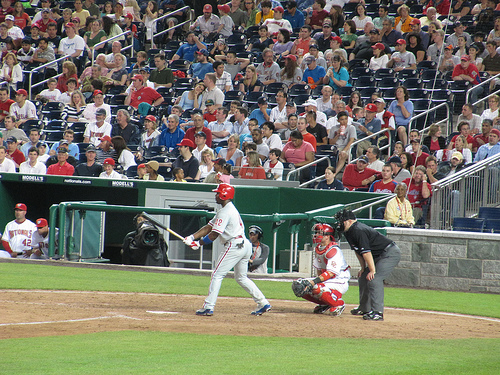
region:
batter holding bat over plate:
[138, 173, 281, 320]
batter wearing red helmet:
[138, 170, 276, 317]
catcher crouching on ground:
[288, 218, 352, 319]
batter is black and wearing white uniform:
[140, 176, 278, 326]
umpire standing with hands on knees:
[330, 202, 401, 327]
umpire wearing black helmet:
[331, 201, 410, 328]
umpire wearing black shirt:
[328, 202, 401, 326]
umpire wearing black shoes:
[333, 195, 412, 337]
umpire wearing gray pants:
[332, 201, 399, 323]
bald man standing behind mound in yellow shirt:
[381, 177, 421, 227]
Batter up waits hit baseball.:
[142, 181, 278, 328]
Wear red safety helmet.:
[210, 179, 254, 239]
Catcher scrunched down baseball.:
[289, 216, 357, 323]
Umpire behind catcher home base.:
[332, 206, 405, 333]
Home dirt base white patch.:
[22, 259, 192, 373]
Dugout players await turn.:
[4, 187, 87, 275]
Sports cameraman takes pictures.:
[114, 206, 179, 263]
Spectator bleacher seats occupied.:
[79, 75, 402, 170]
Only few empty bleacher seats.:
[345, 62, 459, 106]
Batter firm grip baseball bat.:
[136, 201, 221, 262]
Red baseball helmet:
[208, 179, 237, 205]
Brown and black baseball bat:
[111, 198, 223, 269]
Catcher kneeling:
[294, 225, 371, 315]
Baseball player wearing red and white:
[135, 169, 284, 321]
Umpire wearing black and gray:
[329, 205, 416, 314]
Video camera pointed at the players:
[117, 206, 199, 288]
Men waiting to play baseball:
[2, 206, 62, 256]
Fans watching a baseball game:
[97, 44, 377, 210]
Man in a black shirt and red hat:
[170, 135, 202, 175]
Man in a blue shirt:
[247, 93, 278, 127]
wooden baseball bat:
[131, 203, 208, 268]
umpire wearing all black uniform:
[330, 203, 416, 321]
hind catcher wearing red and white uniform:
[289, 221, 364, 333]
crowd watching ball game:
[162, 50, 382, 168]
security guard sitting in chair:
[382, 174, 432, 232]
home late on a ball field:
[113, 281, 198, 362]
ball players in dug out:
[3, 171, 77, 271]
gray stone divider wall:
[399, 218, 495, 314]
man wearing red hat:
[59, 18, 90, 45]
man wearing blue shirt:
[303, 52, 333, 96]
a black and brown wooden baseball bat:
[137, 209, 186, 241]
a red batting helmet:
[208, 180, 235, 201]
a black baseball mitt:
[288, 276, 313, 297]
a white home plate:
[141, 306, 182, 316]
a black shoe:
[361, 307, 384, 323]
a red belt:
[218, 231, 248, 246]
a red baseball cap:
[11, 200, 31, 213]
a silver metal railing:
[403, 100, 451, 150]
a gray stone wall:
[378, 226, 498, 295]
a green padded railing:
[44, 196, 352, 261]